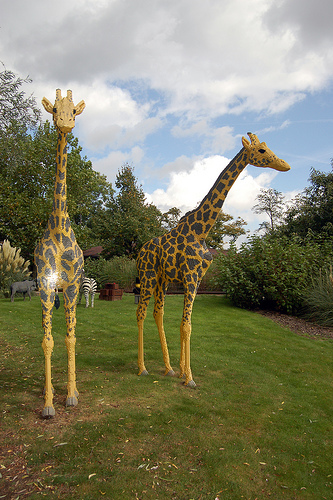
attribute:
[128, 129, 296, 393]
giraffe — standing, large, spotted, black ad brown, gray, yellow, fake, statue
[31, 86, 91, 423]
giraffe — standing, large, gray, yellow., fake, statue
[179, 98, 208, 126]
cloud — white, fluffy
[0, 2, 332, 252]
sky — blue, white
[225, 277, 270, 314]
bush — green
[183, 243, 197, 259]
spot — brown, black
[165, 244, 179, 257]
spot — brown, black, gray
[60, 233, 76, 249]
spot — brown, black, gray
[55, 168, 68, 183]
spot — brown, black, gray